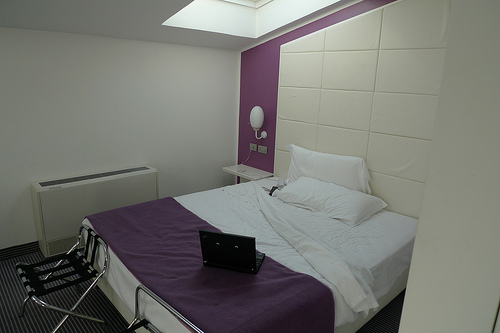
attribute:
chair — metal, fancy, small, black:
[14, 223, 108, 330]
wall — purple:
[240, 0, 400, 173]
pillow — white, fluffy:
[273, 174, 390, 227]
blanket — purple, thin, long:
[87, 198, 335, 333]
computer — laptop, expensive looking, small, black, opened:
[196, 226, 267, 274]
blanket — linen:
[174, 178, 379, 328]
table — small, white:
[220, 159, 274, 191]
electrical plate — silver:
[257, 143, 270, 157]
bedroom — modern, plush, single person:
[1, 0, 499, 331]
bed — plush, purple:
[78, 175, 419, 332]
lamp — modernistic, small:
[245, 102, 270, 141]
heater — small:
[30, 162, 159, 259]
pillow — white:
[283, 139, 373, 199]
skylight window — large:
[160, 0, 340, 39]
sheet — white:
[259, 173, 417, 332]